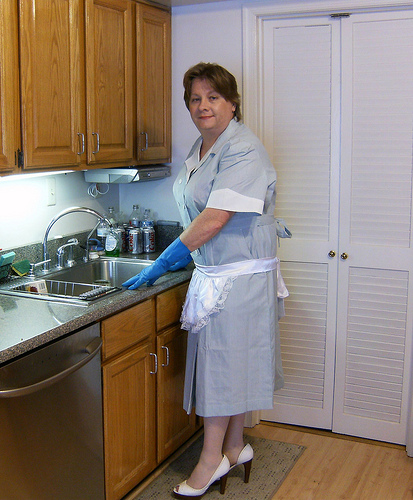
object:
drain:
[6, 275, 118, 301]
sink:
[2, 258, 160, 300]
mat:
[131, 431, 309, 500]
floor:
[125, 409, 413, 500]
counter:
[0, 249, 196, 366]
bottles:
[104, 222, 156, 257]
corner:
[98, 180, 144, 250]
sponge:
[9, 259, 32, 277]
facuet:
[42, 205, 112, 272]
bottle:
[96, 219, 109, 249]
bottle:
[129, 204, 141, 226]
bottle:
[140, 209, 152, 227]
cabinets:
[0, 0, 172, 178]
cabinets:
[100, 280, 197, 500]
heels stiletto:
[172, 441, 253, 500]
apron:
[178, 255, 290, 334]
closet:
[254, 4, 410, 449]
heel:
[218, 470, 229, 494]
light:
[0, 169, 75, 181]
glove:
[121, 236, 194, 291]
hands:
[121, 262, 163, 290]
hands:
[167, 253, 193, 272]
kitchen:
[0, 0, 413, 500]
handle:
[149, 352, 159, 375]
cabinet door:
[103, 342, 157, 500]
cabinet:
[0, 321, 106, 500]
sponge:
[0, 251, 15, 277]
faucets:
[41, 205, 105, 272]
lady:
[120, 62, 293, 500]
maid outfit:
[169, 118, 294, 419]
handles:
[77, 132, 101, 155]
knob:
[340, 252, 348, 259]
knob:
[328, 250, 336, 258]